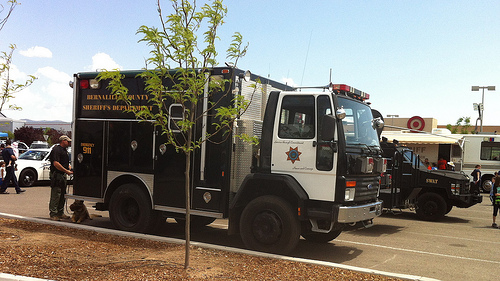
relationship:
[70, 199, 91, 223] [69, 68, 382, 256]
dog under truck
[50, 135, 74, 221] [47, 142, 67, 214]
man in fatigues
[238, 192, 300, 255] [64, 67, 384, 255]
tire on side of truck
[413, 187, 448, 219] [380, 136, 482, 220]
tire on side of truck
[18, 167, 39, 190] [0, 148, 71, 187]
tire on side police car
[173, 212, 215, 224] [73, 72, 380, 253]
tire on side of vehicle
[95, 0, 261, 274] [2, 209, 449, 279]
tree in flower bed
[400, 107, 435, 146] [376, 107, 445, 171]
logo on side of building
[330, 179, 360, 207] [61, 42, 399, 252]
headlight on truck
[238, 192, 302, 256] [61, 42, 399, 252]
wheel on truck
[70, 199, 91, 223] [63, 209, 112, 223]
dog resting in shade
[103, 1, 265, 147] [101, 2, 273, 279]
green leaves on tree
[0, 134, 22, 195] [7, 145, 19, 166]
man holding child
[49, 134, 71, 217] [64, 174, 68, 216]
man holding leash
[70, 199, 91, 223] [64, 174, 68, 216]
dog on leash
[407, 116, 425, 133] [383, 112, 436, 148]
logo on building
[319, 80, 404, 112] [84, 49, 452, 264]
lights on top of truck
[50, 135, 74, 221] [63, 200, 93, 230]
man standing with dog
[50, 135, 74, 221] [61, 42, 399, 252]
man next to truck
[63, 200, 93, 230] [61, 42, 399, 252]
dog next to truck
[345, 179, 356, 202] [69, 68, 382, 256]
lights on truck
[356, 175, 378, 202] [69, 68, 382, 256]
grill on truck